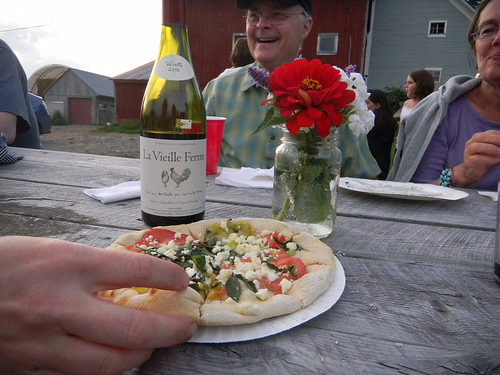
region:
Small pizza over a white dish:
[84, 207, 346, 357]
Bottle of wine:
[128, 1, 225, 235]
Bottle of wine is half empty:
[134, 1, 212, 229]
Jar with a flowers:
[255, 41, 356, 241]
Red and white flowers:
[260, 53, 377, 144]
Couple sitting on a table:
[195, 7, 497, 201]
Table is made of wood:
[7, 135, 497, 373]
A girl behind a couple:
[390, 60, 433, 167]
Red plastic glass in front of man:
[200, 107, 227, 177]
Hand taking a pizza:
[2, 212, 353, 373]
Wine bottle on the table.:
[126, 3, 223, 222]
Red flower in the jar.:
[264, 48, 354, 138]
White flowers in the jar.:
[333, 66, 378, 137]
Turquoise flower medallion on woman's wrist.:
[435, 166, 457, 191]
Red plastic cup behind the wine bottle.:
[192, 106, 231, 175]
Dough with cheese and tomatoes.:
[91, 213, 335, 313]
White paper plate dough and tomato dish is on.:
[95, 222, 357, 348]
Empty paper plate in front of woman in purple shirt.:
[338, 166, 470, 206]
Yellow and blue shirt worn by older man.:
[214, 66, 365, 177]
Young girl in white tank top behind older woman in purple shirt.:
[394, 61, 431, 143]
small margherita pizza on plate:
[76, 203, 357, 342]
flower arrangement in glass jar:
[245, 50, 382, 247]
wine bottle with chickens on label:
[117, 3, 207, 230]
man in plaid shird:
[190, 2, 384, 184]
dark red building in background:
[149, 0, 366, 121]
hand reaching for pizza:
[0, 205, 196, 365]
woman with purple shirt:
[393, 5, 498, 195]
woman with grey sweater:
[398, 8, 492, 196]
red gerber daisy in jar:
[265, 54, 365, 221]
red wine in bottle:
[124, 0, 208, 215]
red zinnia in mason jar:
[246, 55, 375, 241]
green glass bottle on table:
[136, 27, 206, 225]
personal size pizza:
[96, 215, 336, 325]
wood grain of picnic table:
[359, 216, 479, 359]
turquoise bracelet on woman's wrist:
[437, 163, 452, 189]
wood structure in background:
[39, 65, 116, 130]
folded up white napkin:
[82, 177, 144, 205]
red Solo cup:
[205, 112, 225, 173]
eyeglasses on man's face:
[240, 7, 301, 24]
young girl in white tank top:
[397, 67, 435, 127]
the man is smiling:
[224, 3, 337, 71]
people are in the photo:
[188, 4, 495, 219]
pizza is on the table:
[41, 203, 411, 352]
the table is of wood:
[368, 200, 498, 357]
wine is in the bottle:
[128, 0, 257, 230]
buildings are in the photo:
[357, 10, 484, 107]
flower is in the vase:
[259, 61, 397, 289]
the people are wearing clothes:
[181, 49, 483, 174]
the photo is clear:
[3, 5, 499, 371]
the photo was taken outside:
[3, 2, 491, 360]